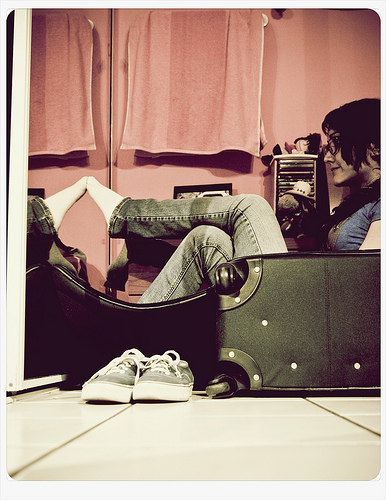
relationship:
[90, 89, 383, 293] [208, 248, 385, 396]
woman sitting in suitcase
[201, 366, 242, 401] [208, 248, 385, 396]
wheel on suitcase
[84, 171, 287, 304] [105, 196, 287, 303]
legs in blue jeans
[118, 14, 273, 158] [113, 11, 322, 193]
towel hanging on wall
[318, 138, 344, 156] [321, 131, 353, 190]
glasses on face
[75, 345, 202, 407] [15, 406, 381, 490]
sneakers on floor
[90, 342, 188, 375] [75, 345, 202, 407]
laces on sneakers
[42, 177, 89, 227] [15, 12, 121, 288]
foot reflection in mirror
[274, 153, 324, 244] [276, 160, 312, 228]
rack with discs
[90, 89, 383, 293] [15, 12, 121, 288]
woman sitting by mirror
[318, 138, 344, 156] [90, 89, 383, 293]
eyeglasses on woman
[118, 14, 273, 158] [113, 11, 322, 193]
towel hanging from wall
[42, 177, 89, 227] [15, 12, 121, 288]
foot reflection on mirror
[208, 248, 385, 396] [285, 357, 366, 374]
luggage has silver rivets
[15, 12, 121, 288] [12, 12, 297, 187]
mirror on wall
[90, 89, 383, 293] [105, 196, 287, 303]
woman has blue jeans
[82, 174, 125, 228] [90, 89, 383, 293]
sock on woman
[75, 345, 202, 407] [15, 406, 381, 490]
sneakers on ground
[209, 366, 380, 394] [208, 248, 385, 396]
bottom of suitcase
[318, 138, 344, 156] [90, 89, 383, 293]
glasses on woman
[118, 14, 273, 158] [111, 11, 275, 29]
towel hanging on rack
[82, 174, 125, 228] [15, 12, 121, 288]
sock reflection in mirror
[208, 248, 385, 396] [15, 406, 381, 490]
suitcase touching floor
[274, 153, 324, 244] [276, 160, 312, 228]
tower with cds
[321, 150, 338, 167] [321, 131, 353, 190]
nose on front face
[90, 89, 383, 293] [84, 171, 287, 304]
woman wearing blue jeans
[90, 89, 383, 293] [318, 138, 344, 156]
woman wearing glasses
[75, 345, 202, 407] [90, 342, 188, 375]
shoes with laces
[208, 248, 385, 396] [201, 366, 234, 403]
luggage has wheel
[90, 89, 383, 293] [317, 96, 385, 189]
woman with short hair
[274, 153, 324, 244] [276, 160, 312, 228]
tower has cds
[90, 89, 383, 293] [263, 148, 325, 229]
person reading a book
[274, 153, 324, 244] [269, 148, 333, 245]
dvds on shelf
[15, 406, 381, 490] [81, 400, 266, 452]
floor with tile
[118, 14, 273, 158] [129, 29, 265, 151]
towel on window